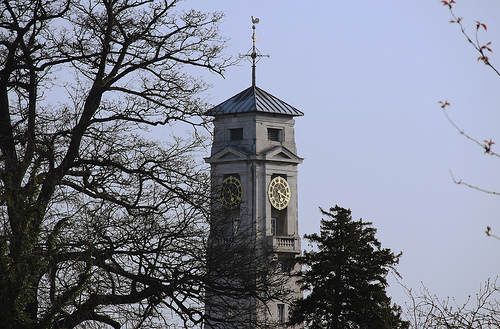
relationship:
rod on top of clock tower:
[235, 13, 273, 84] [197, 11, 308, 325]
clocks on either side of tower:
[219, 174, 292, 209] [200, 14, 306, 324]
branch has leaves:
[442, 98, 499, 152] [483, 137, 492, 155]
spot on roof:
[234, 81, 273, 98] [186, 82, 316, 114]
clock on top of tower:
[273, 171, 293, 201] [201, 13, 316, 326]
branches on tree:
[51, 21, 170, 214] [0, 3, 237, 319]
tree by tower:
[297, 199, 412, 327] [200, 14, 306, 324]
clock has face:
[267, 176, 291, 210] [271, 175, 292, 207]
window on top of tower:
[219, 126, 251, 142] [209, 11, 311, 323]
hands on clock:
[274, 174, 291, 200] [265, 164, 299, 212]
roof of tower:
[222, 86, 285, 113] [205, 17, 300, 327]